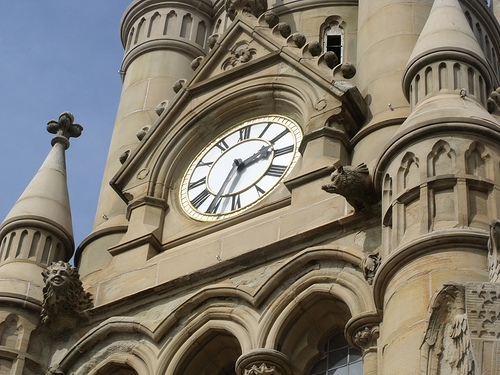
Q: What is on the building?
A: A clock.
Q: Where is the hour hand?
A: On the clock.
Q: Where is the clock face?
A: On the hand.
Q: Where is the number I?
A: On the clock.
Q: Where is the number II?
A: On the clock.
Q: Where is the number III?
A: On the clock.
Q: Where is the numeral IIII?
A: On the clock.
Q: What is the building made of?
A: Stone.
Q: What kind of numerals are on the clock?
A: Roman.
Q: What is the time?
A: 2:35.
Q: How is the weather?
A: Sunny.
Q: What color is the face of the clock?
A: White.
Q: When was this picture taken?
A: Daytime.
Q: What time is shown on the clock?
A: 2:34.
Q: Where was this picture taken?
A: A church.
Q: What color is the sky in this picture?
A: Blue.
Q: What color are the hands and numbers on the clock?
A: Black.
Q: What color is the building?
A: Tan.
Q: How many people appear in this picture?
A: Zero.